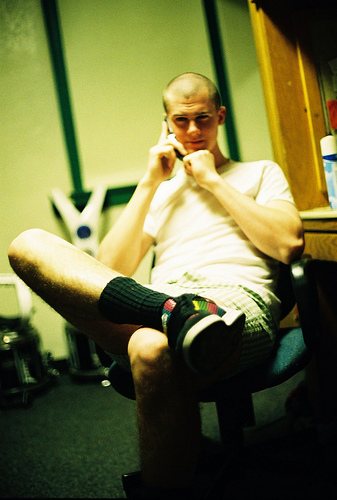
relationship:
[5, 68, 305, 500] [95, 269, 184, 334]
man wearing sock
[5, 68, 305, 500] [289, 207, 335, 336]
man sitting at desk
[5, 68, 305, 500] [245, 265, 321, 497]
man sitting in chair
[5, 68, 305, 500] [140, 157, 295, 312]
man wearing shirt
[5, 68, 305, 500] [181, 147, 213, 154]
man resting chin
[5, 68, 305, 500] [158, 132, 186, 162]
man talking on phone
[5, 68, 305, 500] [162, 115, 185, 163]
man talking on cellphone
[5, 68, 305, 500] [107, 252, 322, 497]
man sitting in chair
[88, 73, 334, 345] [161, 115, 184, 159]
man on cell phone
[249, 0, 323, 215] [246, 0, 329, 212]
wood panel on wall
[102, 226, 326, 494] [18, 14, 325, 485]
chair in a room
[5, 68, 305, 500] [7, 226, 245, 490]
man crossing legs